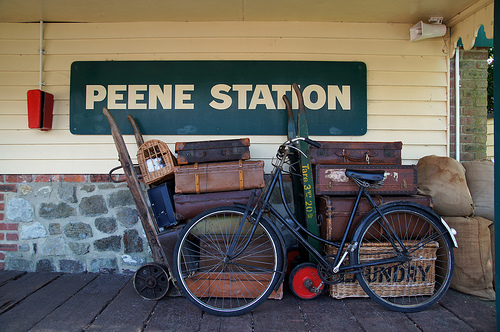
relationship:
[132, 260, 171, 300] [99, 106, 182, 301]
wheel on dolly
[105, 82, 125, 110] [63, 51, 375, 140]
e on sign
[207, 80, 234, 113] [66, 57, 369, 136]
letter s on sign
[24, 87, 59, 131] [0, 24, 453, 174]
object on wall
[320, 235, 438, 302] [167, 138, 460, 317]
trunk basket behind bicycle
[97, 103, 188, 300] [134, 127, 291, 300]
dolly near pile